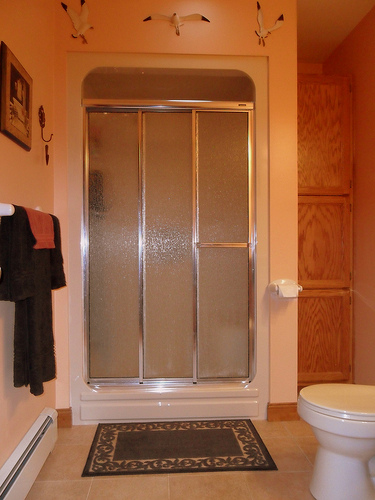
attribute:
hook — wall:
[37, 107, 52, 143]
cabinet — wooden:
[295, 189, 353, 289]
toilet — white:
[298, 378, 371, 498]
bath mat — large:
[82, 417, 278, 472]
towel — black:
[24, 203, 57, 253]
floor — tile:
[49, 424, 308, 497]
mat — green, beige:
[79, 418, 277, 476]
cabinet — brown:
[58, 105, 367, 376]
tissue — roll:
[277, 285, 301, 296]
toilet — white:
[293, 378, 374, 499]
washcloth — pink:
[17, 200, 53, 247]